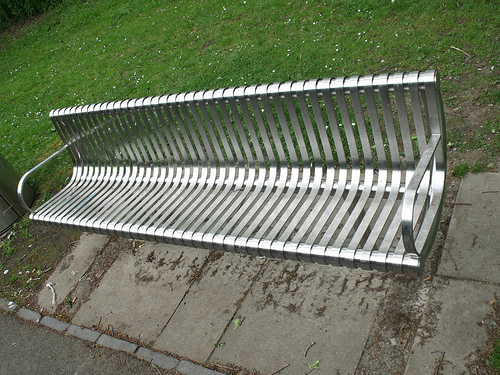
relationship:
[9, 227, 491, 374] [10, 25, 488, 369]
leaves in patio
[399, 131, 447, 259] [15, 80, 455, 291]
arm on bench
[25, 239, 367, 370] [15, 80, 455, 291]
cement under bench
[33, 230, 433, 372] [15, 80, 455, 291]
pavers next to bench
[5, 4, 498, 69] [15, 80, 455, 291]
grass behind bench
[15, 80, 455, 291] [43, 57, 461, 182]
bench has back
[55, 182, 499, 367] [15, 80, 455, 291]
slabs under bench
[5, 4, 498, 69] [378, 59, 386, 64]
grass covered with flower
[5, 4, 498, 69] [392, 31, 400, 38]
grass covered with flower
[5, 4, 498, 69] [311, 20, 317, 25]
grass covered with flower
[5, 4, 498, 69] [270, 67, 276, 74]
grass covered with flower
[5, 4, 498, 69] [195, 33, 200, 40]
grass covered with flower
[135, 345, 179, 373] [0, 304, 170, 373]
brick between pavement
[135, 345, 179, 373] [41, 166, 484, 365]
brick between concrete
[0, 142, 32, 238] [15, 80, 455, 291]
container next to bench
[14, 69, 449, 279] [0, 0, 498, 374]
silver bench in park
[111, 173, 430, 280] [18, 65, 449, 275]
metal through slats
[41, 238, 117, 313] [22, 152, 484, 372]
concrete line on pad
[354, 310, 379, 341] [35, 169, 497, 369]
line on concrete pad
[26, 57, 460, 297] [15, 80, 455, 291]
slats on bench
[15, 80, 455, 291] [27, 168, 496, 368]
bench on patio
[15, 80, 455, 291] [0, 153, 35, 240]
bench beside trash can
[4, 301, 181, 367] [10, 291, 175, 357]
road with trim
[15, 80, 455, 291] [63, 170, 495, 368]
bench on platform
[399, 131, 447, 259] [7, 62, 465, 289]
arm at end of bench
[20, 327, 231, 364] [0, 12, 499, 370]
concrete next to pavers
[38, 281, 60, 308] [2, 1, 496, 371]
garbage on patio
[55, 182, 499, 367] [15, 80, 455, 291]
slabs on bench